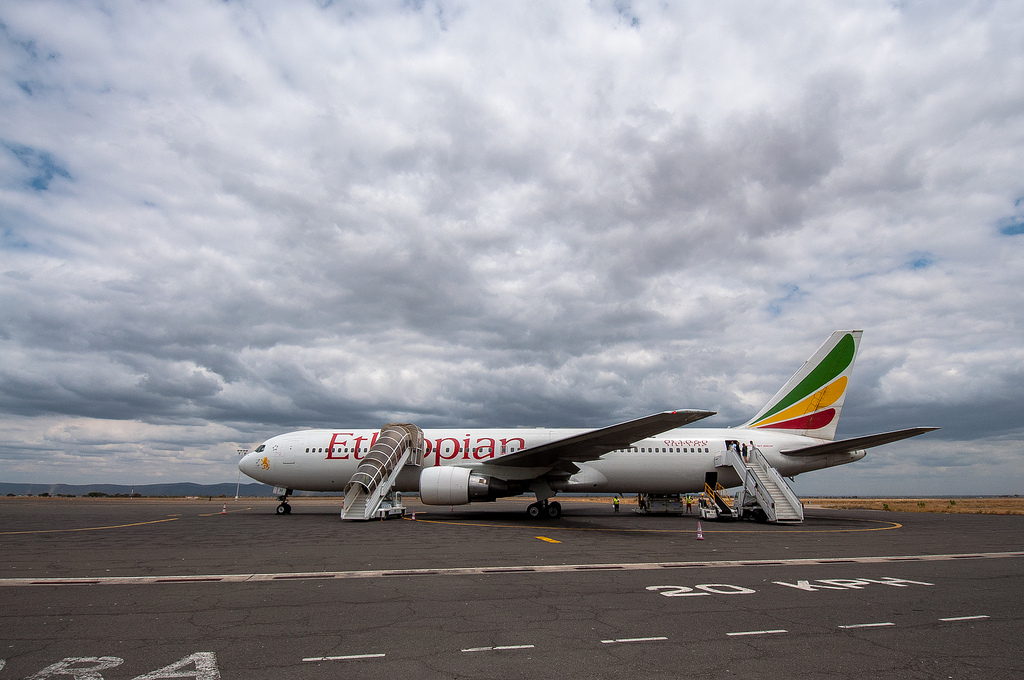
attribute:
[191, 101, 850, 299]
sky — white, cloudy, blue, grey, dark, light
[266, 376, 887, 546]
plane — white, parked, red, yellow, still, sitting, close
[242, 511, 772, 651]
runway — black, paved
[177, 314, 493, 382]
cloud — heavy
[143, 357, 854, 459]
jet — predominantly white